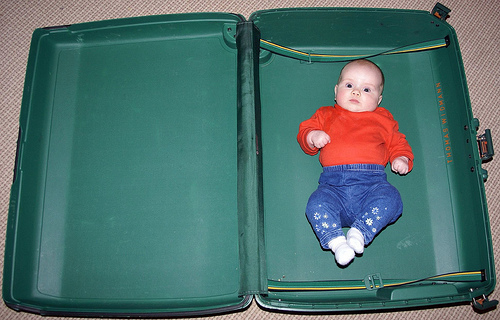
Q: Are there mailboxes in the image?
A: No, there are no mailboxes.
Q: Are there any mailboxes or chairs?
A: No, there are no mailboxes or chairs.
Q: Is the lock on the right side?
A: Yes, the lock is on the right of the image.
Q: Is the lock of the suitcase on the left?
A: No, the lock is on the right of the image.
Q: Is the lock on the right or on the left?
A: The lock is on the right of the image.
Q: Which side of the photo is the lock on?
A: The lock is on the right of the image.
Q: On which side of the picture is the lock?
A: The lock is on the right of the image.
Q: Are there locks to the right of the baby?
A: Yes, there is a lock to the right of the baby.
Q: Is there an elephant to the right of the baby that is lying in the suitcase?
A: No, there is a lock to the right of the baby.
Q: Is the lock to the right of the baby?
A: Yes, the lock is to the right of the baby.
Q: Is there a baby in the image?
A: Yes, there is a baby.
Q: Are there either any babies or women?
A: Yes, there is a baby.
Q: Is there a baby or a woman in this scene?
A: Yes, there is a baby.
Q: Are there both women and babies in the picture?
A: No, there is a baby but no women.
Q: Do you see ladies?
A: No, there are no ladies.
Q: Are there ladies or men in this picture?
A: No, there are no ladies or men.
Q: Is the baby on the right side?
A: Yes, the baby is on the right of the image.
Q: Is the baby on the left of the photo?
A: No, the baby is on the right of the image.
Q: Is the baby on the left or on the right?
A: The baby is on the right of the image.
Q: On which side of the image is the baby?
A: The baby is on the right of the image.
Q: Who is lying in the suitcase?
A: The baby is lying in the suitcase.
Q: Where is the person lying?
A: The baby is lying in the suitcase.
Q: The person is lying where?
A: The baby is lying in the suitcase.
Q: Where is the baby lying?
A: The baby is lying in the suitcase.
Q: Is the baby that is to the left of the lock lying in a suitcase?
A: Yes, the baby is lying in a suitcase.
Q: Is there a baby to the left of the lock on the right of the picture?
A: Yes, there is a baby to the left of the lock.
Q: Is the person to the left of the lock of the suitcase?
A: Yes, the baby is to the left of the lock.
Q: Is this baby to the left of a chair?
A: No, the baby is to the left of the lock.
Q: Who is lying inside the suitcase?
A: The baby is lying inside the suitcase.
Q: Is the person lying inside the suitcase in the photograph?
A: Yes, the baby is lying inside the suitcase.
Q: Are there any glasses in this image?
A: No, there are no glasses.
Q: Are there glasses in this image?
A: No, there are no glasses.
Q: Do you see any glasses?
A: No, there are no glasses.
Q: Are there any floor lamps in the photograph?
A: No, there are no floor lamps.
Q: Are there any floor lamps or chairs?
A: No, there are no floor lamps or chairs.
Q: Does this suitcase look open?
A: Yes, the suitcase is open.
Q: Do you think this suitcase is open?
A: Yes, the suitcase is open.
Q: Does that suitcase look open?
A: Yes, the suitcase is open.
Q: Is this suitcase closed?
A: No, the suitcase is open.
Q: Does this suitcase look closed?
A: No, the suitcase is open.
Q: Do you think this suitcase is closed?
A: No, the suitcase is open.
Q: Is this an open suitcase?
A: Yes, this is an open suitcase.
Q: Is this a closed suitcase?
A: No, this is an open suitcase.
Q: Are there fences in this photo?
A: No, there are no fences.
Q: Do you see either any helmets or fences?
A: No, there are no fences or helmets.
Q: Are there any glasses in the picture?
A: No, there are no glasses.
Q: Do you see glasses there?
A: No, there are no glasses.